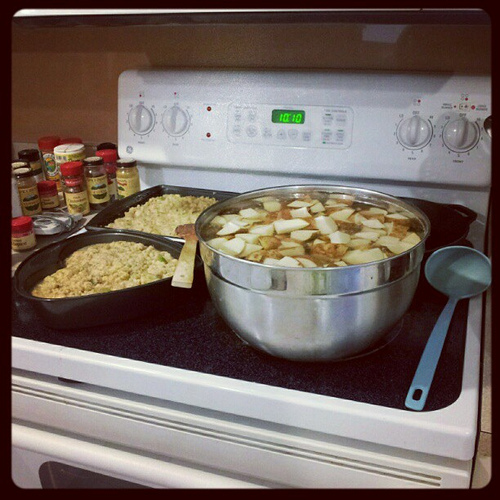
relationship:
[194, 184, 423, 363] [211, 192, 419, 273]
bowl of potatoes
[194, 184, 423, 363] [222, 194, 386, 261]
bowl of water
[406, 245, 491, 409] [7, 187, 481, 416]
spoon on stove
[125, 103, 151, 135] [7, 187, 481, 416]
knob on stove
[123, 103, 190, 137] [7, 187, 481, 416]
knobs on stove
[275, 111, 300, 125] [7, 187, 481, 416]
letters on stove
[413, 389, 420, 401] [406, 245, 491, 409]
hole in spoon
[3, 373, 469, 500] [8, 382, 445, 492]
lines on door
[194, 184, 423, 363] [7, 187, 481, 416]
pot on stove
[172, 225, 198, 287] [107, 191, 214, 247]
spoon in food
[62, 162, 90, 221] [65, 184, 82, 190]
container of herbs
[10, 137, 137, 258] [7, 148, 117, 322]
spices on counter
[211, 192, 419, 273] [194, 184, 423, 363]
potatoes in bowl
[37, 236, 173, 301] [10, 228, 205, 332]
casserole in casserole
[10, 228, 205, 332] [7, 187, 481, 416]
casserole on stove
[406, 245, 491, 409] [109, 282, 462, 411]
spoon on surface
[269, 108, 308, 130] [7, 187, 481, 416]
clock on stove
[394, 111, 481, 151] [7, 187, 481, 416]
knobs on stove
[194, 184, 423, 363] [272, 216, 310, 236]
bowl has potatoes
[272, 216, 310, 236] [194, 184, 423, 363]
potatoes in bowl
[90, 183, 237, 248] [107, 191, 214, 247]
pan of food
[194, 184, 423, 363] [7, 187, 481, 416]
bowl on stove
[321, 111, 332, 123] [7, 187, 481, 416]
button on stove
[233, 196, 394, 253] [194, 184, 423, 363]
potatoes in bowl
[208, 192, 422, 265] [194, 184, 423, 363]
water in bowl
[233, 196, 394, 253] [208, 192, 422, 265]
potatoes in water